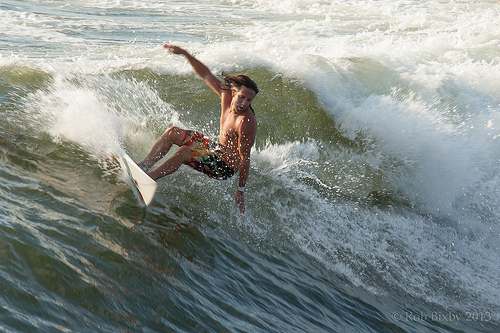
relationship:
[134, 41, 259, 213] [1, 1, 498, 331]
surfer on ocean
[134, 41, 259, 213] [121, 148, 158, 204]
surfer on surfboard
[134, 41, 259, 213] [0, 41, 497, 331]
surfer on wave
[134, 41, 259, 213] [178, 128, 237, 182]
surfer wearing shorts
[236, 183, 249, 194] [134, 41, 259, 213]
watch on surfer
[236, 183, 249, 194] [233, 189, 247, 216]
watch on hand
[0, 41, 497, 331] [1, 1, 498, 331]
wave breaking in ocean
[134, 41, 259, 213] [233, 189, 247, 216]
surfer has hand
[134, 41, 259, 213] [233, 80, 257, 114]
surfer has head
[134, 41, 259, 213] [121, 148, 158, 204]
surfer riding surfboard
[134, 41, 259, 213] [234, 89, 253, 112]
surfer has face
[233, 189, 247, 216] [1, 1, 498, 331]
hand above ocean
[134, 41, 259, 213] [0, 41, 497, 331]
surfer surfing wave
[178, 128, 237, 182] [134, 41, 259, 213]
shorts on surfer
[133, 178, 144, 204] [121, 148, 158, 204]
logo on surfboard